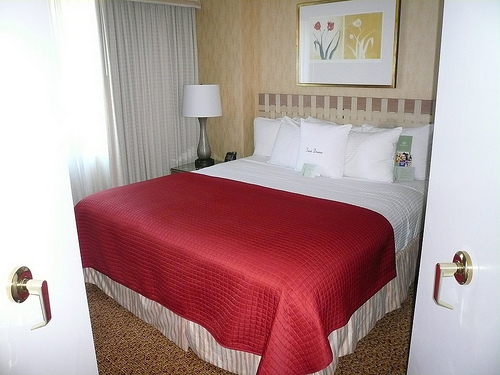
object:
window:
[55, 0, 98, 160]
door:
[0, 3, 95, 374]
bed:
[72, 124, 434, 374]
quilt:
[72, 171, 397, 375]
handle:
[431, 261, 457, 311]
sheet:
[76, 155, 423, 375]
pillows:
[344, 127, 401, 184]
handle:
[7, 266, 52, 332]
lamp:
[183, 85, 223, 164]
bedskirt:
[74, 235, 420, 374]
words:
[305, 147, 323, 154]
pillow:
[295, 117, 353, 179]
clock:
[225, 151, 237, 161]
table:
[170, 159, 224, 176]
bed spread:
[74, 155, 427, 375]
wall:
[212, 36, 279, 81]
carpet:
[82, 281, 415, 374]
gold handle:
[432, 251, 474, 311]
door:
[396, 0, 499, 374]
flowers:
[303, 12, 383, 59]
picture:
[297, 1, 401, 88]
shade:
[182, 84, 223, 118]